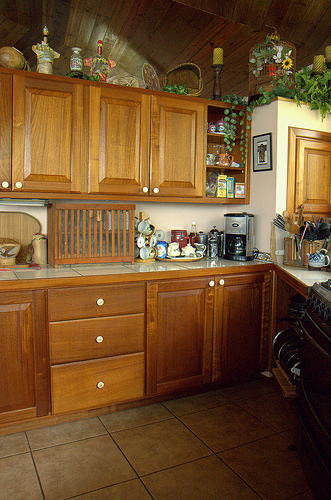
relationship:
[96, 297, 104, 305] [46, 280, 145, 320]
knob on drawer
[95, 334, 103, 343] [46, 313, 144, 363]
knob on drawer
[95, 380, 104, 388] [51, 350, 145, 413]
knob on drawer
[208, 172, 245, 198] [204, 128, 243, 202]
food on shelves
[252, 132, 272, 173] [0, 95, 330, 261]
decoration on wall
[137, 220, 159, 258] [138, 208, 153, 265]
mugs on holder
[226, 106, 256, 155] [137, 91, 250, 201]
leaves on cabinet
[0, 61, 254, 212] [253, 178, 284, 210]
cabinets on wall